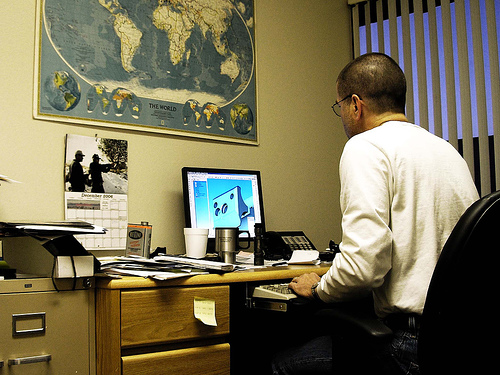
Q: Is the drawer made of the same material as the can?
A: No, the drawer is made of wood and the can is made of metal.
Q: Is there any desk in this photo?
A: Yes, there is a desk.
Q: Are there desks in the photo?
A: Yes, there is a desk.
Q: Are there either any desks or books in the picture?
A: Yes, there is a desk.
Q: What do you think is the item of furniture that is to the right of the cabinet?
A: The piece of furniture is a desk.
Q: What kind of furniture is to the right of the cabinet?
A: The piece of furniture is a desk.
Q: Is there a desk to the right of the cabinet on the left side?
A: Yes, there is a desk to the right of the cabinet.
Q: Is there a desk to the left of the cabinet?
A: No, the desk is to the right of the cabinet.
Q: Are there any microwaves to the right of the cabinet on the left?
A: No, there is a desk to the right of the cabinet.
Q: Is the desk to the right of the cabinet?
A: Yes, the desk is to the right of the cabinet.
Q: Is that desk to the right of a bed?
A: No, the desk is to the right of the cabinet.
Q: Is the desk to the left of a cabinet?
A: No, the desk is to the right of a cabinet.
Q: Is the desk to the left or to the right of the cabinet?
A: The desk is to the right of the cabinet.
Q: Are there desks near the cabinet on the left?
A: Yes, there is a desk near the cabinet.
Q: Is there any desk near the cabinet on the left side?
A: Yes, there is a desk near the cabinet.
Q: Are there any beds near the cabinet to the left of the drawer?
A: No, there is a desk near the cabinet.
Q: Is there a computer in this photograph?
A: Yes, there is a computer.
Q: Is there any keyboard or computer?
A: Yes, there is a computer.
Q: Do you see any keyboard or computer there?
A: Yes, there is a computer.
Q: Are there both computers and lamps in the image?
A: No, there is a computer but no lamps.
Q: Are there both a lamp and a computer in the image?
A: No, there is a computer but no lamps.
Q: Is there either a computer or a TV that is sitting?
A: Yes, the computer is sitting.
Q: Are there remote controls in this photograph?
A: No, there are no remote controls.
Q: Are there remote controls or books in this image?
A: No, there are no remote controls or books.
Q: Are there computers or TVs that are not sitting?
A: No, there is a computer but it is sitting.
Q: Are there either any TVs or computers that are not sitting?
A: No, there is a computer but it is sitting.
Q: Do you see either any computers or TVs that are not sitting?
A: No, there is a computer but it is sitting.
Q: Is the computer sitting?
A: Yes, the computer is sitting.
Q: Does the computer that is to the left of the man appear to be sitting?
A: Yes, the computer is sitting.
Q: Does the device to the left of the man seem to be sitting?
A: Yes, the computer is sitting.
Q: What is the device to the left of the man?
A: The device is a computer.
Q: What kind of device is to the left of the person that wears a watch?
A: The device is a computer.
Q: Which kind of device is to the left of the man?
A: The device is a computer.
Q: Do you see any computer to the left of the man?
A: Yes, there is a computer to the left of the man.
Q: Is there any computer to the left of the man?
A: Yes, there is a computer to the left of the man.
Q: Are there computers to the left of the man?
A: Yes, there is a computer to the left of the man.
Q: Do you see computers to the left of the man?
A: Yes, there is a computer to the left of the man.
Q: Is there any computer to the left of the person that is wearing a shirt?
A: Yes, there is a computer to the left of the man.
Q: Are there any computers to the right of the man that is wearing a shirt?
A: No, the computer is to the left of the man.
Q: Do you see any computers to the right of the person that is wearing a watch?
A: No, the computer is to the left of the man.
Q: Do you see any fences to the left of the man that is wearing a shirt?
A: No, there is a computer to the left of the man.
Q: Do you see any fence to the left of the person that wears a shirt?
A: No, there is a computer to the left of the man.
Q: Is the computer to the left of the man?
A: Yes, the computer is to the left of the man.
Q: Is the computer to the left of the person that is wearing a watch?
A: Yes, the computer is to the left of the man.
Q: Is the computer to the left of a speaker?
A: No, the computer is to the left of the man.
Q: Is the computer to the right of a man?
A: No, the computer is to the left of a man.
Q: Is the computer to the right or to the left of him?
A: The computer is to the left of the man.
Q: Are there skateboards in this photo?
A: No, there are no skateboards.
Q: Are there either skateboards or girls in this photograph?
A: No, there are no skateboards or girls.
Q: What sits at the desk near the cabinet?
A: The jeans sit at the desk.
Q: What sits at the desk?
A: The jeans sit at the desk.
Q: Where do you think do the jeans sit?
A: The jeans sit at the desk.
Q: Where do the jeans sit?
A: The jeans sit at the desk.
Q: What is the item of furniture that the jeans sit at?
A: The piece of furniture is a desk.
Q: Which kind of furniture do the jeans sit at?
A: The jeans sit at the desk.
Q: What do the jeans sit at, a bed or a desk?
A: The jeans sit at a desk.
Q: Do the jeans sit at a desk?
A: Yes, the jeans sit at a desk.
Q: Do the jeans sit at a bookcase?
A: No, the jeans sit at a desk.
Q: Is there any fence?
A: No, there are no fences.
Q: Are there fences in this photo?
A: No, there are no fences.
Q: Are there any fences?
A: No, there are no fences.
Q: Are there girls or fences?
A: No, there are no fences or girls.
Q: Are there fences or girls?
A: No, there are no fences or girls.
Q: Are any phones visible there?
A: Yes, there is a phone.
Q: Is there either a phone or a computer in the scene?
A: Yes, there is a phone.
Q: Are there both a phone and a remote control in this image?
A: No, there is a phone but no remote controls.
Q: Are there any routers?
A: No, there are no routers.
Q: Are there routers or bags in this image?
A: No, there are no routers or bags.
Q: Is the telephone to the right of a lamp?
A: No, the telephone is to the right of the cup.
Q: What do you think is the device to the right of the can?
A: The device is a phone.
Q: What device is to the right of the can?
A: The device is a phone.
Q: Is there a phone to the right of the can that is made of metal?
A: Yes, there is a phone to the right of the can.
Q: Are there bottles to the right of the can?
A: No, there is a phone to the right of the can.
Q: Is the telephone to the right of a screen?
A: No, the telephone is to the right of the can.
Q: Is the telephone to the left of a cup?
A: No, the telephone is to the right of a cup.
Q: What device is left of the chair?
A: The device is a phone.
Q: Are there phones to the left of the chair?
A: Yes, there is a phone to the left of the chair.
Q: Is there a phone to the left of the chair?
A: Yes, there is a phone to the left of the chair.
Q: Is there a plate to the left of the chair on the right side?
A: No, there is a phone to the left of the chair.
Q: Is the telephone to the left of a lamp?
A: No, the telephone is to the left of a chair.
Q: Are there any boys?
A: No, there are no boys.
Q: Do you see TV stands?
A: No, there are no TV stands.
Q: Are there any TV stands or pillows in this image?
A: No, there are no TV stands or pillows.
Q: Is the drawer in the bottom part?
A: Yes, the drawer is in the bottom of the image.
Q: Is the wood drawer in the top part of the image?
A: No, the drawer is in the bottom of the image.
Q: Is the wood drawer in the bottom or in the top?
A: The drawer is in the bottom of the image.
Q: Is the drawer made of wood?
A: Yes, the drawer is made of wood.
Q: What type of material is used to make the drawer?
A: The drawer is made of wood.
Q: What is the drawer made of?
A: The drawer is made of wood.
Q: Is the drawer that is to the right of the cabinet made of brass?
A: No, the drawer is made of wood.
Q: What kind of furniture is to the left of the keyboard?
A: The piece of furniture is a drawer.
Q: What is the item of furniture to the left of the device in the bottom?
A: The piece of furniture is a drawer.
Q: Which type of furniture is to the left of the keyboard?
A: The piece of furniture is a drawer.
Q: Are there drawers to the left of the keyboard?
A: Yes, there is a drawer to the left of the keyboard.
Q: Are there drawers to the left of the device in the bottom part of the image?
A: Yes, there is a drawer to the left of the keyboard.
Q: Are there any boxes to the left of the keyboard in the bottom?
A: No, there is a drawer to the left of the keyboard.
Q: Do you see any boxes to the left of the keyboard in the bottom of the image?
A: No, there is a drawer to the left of the keyboard.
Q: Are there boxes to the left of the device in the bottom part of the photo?
A: No, there is a drawer to the left of the keyboard.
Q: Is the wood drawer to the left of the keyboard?
A: Yes, the drawer is to the left of the keyboard.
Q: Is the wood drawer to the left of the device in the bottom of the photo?
A: Yes, the drawer is to the left of the keyboard.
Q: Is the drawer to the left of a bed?
A: No, the drawer is to the left of the keyboard.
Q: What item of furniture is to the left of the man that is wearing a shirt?
A: The piece of furniture is a drawer.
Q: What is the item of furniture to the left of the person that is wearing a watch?
A: The piece of furniture is a drawer.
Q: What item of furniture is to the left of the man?
A: The piece of furniture is a drawer.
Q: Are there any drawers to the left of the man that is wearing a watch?
A: Yes, there is a drawer to the left of the man.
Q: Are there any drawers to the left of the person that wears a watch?
A: Yes, there is a drawer to the left of the man.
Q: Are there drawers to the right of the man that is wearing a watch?
A: No, the drawer is to the left of the man.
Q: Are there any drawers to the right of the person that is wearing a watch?
A: No, the drawer is to the left of the man.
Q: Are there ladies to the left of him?
A: No, there is a drawer to the left of the man.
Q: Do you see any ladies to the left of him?
A: No, there is a drawer to the left of the man.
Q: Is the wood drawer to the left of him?
A: Yes, the drawer is to the left of a man.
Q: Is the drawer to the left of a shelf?
A: No, the drawer is to the left of a man.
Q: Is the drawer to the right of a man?
A: No, the drawer is to the left of a man.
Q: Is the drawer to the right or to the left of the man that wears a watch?
A: The drawer is to the left of the man.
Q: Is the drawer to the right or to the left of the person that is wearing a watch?
A: The drawer is to the left of the man.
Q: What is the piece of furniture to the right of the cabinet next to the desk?
A: The piece of furniture is a drawer.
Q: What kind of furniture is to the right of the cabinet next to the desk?
A: The piece of furniture is a drawer.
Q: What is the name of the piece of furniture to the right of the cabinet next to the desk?
A: The piece of furniture is a drawer.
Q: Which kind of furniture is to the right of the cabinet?
A: The piece of furniture is a drawer.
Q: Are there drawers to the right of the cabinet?
A: Yes, there is a drawer to the right of the cabinet.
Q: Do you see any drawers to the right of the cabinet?
A: Yes, there is a drawer to the right of the cabinet.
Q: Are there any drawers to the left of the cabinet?
A: No, the drawer is to the right of the cabinet.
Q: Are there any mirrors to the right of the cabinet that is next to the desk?
A: No, there is a drawer to the right of the cabinet.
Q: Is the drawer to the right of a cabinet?
A: Yes, the drawer is to the right of a cabinet.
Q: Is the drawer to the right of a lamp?
A: No, the drawer is to the right of a cabinet.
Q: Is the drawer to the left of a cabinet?
A: No, the drawer is to the right of a cabinet.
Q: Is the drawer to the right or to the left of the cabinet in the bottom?
A: The drawer is to the right of the cabinet.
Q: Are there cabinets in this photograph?
A: Yes, there is a cabinet.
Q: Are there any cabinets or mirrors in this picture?
A: Yes, there is a cabinet.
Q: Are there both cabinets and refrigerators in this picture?
A: No, there is a cabinet but no refrigerators.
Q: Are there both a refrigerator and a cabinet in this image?
A: No, there is a cabinet but no refrigerators.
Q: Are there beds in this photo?
A: No, there are no beds.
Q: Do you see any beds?
A: No, there are no beds.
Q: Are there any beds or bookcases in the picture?
A: No, there are no beds or bookcases.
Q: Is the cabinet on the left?
A: Yes, the cabinet is on the left of the image.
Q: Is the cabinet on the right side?
A: No, the cabinet is on the left of the image.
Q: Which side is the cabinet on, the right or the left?
A: The cabinet is on the left of the image.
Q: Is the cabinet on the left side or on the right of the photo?
A: The cabinet is on the left of the image.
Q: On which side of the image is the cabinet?
A: The cabinet is on the left of the image.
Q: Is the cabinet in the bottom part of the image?
A: Yes, the cabinet is in the bottom of the image.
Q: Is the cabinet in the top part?
A: No, the cabinet is in the bottom of the image.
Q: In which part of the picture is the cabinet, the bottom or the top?
A: The cabinet is in the bottom of the image.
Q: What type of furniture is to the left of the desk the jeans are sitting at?
A: The piece of furniture is a cabinet.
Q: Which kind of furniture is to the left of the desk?
A: The piece of furniture is a cabinet.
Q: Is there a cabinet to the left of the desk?
A: Yes, there is a cabinet to the left of the desk.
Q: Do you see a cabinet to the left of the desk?
A: Yes, there is a cabinet to the left of the desk.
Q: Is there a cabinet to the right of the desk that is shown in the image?
A: No, the cabinet is to the left of the desk.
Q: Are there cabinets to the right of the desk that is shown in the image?
A: No, the cabinet is to the left of the desk.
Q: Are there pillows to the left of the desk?
A: No, there is a cabinet to the left of the desk.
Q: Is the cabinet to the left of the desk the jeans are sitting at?
A: Yes, the cabinet is to the left of the desk.